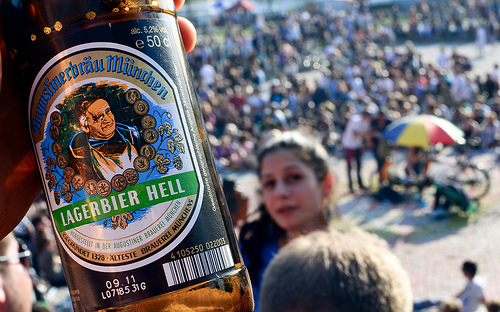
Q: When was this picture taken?
A: Daytime.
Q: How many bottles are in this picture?
A: 1.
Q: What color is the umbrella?
A: Blue, red, yello.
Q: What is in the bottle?
A: Beer.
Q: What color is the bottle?
A: Brown.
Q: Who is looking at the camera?
A: A girl.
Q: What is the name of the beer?
A: Lagerbier Hell.